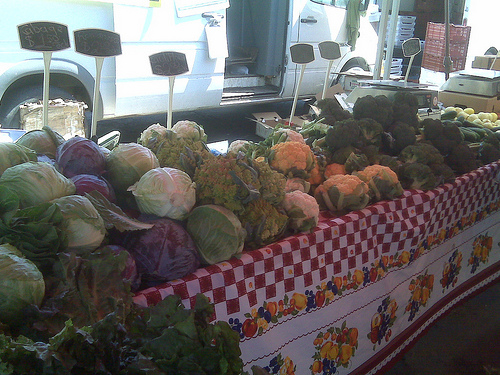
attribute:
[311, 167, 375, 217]
cauliflower — white, yellow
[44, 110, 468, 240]
vegetables — row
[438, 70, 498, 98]
scale — silver, measuring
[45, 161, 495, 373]
tablecloth — red, white, checkered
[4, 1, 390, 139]
truck — white, delivery truck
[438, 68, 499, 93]
scale — silver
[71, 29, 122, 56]
sign — black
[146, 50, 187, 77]
sign — black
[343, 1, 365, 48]
towel — green, hanging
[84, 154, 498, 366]
tablecloth — fruit, checkered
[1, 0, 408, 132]
van — white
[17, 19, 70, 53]
sign — black, sale sign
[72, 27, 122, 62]
sign — sale sign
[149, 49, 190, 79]
sign — sale sign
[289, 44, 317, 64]
sign — sale sign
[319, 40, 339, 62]
sign — sale sign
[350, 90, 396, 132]
broccoli — green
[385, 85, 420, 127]
broccoli — green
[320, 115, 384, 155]
broccoli — green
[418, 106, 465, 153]
broccoli — green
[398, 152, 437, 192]
broccoli — green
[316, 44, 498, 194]
crates — stacked, red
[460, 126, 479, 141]
cucumber — pile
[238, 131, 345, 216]
cauliflower — yellow, white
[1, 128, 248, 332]
cabbage — purple, green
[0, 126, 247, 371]
cabbage — green, purple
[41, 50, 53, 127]
stand — white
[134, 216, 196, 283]
cabbage — large, purple, bottom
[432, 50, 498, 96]
scale — silver